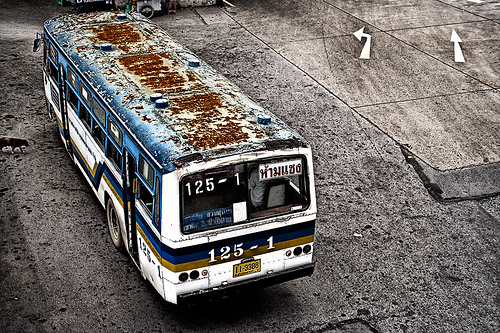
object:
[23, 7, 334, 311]
bus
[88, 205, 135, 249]
wheel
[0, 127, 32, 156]
animal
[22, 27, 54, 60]
mirror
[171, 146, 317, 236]
window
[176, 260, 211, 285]
lights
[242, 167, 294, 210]
person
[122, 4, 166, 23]
road sign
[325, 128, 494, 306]
road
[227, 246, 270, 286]
license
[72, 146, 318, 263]
stripes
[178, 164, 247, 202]
numbers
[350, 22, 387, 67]
arrow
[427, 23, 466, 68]
arrow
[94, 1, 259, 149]
leaves